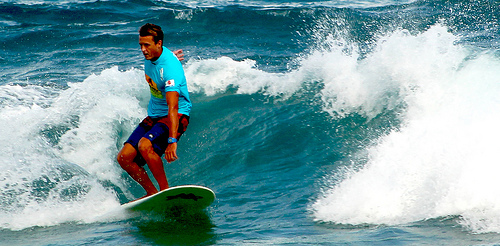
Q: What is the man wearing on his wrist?
A: A watch.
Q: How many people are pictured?
A: One.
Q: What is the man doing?
A: Surfing.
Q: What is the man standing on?
A: A surfboard.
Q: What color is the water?
A: Blue.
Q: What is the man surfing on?
A: Water.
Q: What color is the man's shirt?
A: Blue.